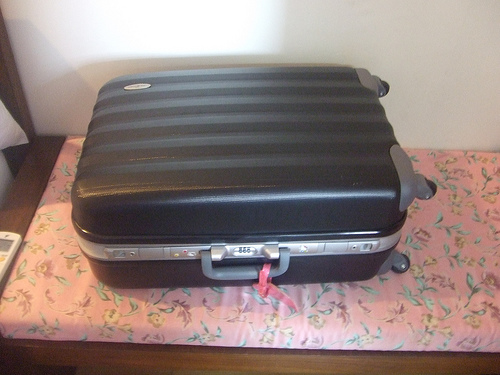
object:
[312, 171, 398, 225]
ground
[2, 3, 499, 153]
wall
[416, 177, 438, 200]
wheel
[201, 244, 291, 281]
gray handle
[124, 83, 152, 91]
disk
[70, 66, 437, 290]
case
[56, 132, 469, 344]
mat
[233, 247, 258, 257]
combination lock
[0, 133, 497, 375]
table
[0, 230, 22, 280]
control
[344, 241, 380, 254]
latch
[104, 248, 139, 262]
latch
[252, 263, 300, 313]
pink ribbon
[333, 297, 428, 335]
mulitcolored flowers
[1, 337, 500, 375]
frame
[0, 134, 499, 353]
cover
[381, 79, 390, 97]
wheel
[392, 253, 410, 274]
wheel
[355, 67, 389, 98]
bracket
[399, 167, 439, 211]
bracket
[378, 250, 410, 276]
bracket